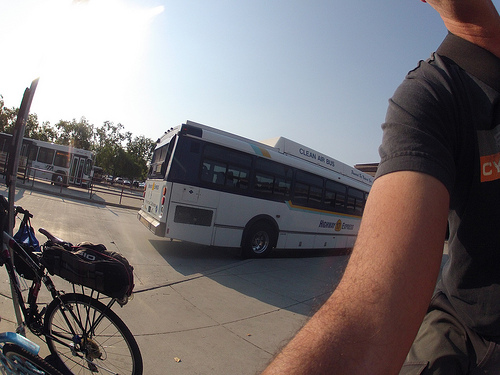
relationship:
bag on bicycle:
[42, 237, 136, 300] [1, 196, 143, 374]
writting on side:
[296, 144, 343, 173] [281, 137, 341, 180]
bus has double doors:
[0, 131, 96, 195] [68, 151, 88, 189]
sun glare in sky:
[4, 1, 175, 123] [1, 0, 384, 118]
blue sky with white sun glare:
[1, 0, 384, 118] [4, 1, 175, 123]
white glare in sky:
[4, 1, 175, 123] [1, 0, 384, 118]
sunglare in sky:
[4, 1, 175, 123] [1, 0, 384, 118]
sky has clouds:
[1, 0, 384, 118] [4, 1, 175, 123]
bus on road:
[138, 121, 354, 258] [0, 200, 143, 238]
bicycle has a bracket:
[1, 196, 143, 374] [41, 276, 128, 356]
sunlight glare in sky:
[4, 1, 175, 123] [1, 0, 384, 118]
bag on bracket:
[42, 237, 136, 300] [41, 276, 128, 356]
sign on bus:
[296, 144, 343, 173] [138, 121, 354, 258]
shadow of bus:
[158, 246, 314, 314] [138, 121, 354, 258]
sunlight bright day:
[4, 1, 175, 123] [0, 1, 498, 374]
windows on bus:
[204, 143, 248, 189] [138, 121, 354, 258]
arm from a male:
[257, 140, 451, 375] [259, 1, 499, 374]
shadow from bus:
[158, 246, 314, 314] [138, 121, 354, 258]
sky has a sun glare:
[1, 0, 384, 118] [4, 1, 175, 123]